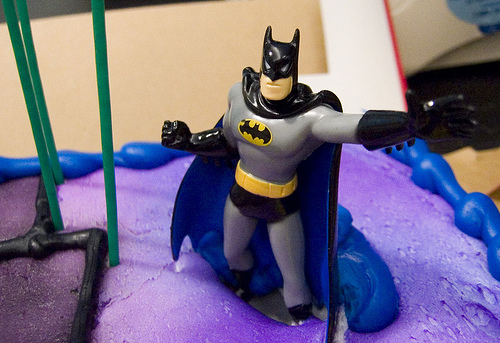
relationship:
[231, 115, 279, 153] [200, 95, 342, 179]
symbol on chest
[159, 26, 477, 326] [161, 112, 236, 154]
batman wearing black gloves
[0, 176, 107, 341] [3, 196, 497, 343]
icing on cake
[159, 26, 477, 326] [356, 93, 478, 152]
batman wears black gloves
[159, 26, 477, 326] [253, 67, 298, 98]
batman wears mask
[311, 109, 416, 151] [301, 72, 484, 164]
arm of an arm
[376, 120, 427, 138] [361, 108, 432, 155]
part of an arm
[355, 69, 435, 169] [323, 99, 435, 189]
part of a hand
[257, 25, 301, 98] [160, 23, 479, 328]
face of a toy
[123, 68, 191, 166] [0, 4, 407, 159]
part of a wall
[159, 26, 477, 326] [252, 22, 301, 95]
batman black face mask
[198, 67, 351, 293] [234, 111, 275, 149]
batman yellow and black logo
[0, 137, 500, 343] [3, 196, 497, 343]
icing on a cake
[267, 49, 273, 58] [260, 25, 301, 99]
light bouncing off batmans head